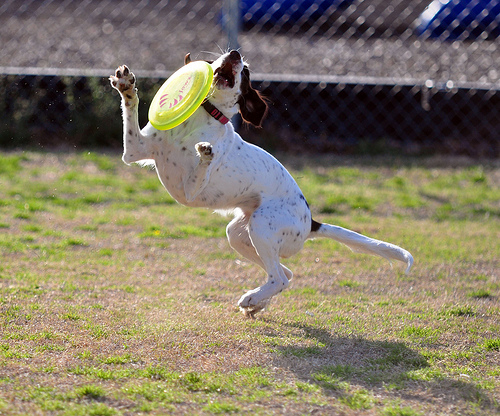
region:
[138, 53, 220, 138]
Frisbee is yellow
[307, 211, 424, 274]
Tail of dog is white and black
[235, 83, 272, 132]
Ear of dog is black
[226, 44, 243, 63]
Nose of dog is black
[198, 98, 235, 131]
Red and black collar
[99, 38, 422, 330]
Dog is white and black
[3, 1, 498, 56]
Field is fenced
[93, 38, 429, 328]
Dog is jumping in the air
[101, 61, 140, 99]
Paw of dog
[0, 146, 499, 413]
Patches of grass on field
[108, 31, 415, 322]
a white dog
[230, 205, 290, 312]
a white dog's leg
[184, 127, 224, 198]
a white dog's leg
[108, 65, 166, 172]
a white dog's leg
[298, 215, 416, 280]
a white dog's tail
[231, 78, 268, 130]
a white dog's ear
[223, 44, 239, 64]
a white dog's nose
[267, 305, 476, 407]
a white dog's shadow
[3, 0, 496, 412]
it is a sunny day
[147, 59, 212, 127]
yellow frisbee with red pattern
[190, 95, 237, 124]
Red dog collar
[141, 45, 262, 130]
Frisbee hitting dog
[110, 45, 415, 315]
White dog with black spots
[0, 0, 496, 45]
Blurry chainlink fence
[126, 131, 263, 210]
Chest of a dog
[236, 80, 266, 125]
Dog's brown left ear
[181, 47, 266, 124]
Face of a dog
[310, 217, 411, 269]
White dog tail with brown patch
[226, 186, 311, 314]
Dog's hind region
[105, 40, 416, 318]
Dog trying to catch Frisbee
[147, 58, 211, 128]
Yellow Frisbee in the air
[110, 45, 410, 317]
White, spotted dog jumping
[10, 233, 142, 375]
Grass with green and dead patches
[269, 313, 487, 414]
Dog shadow on grass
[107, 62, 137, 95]
Dog paw off the ground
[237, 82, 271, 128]
Brown, floppy dog ear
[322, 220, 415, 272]
White dog tail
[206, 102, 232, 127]
Red collar on dog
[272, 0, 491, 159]
Wire fence at edge of grassy field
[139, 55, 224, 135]
the dog toy is a frisbee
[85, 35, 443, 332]
the dog is playing with a frisbee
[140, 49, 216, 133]
the frisbee is neon yellow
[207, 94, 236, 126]
the dog collar is red and black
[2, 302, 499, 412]
the grass is very patchy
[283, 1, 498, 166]
The fence is a chain-link one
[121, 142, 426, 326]
the dog is dark with white spots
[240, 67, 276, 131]
the dog has brown ears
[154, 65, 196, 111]
the frisbee has a red design on it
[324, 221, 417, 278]
Most of the dog's tail is white